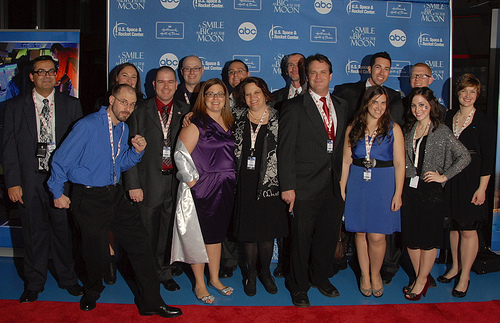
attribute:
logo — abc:
[235, 21, 259, 45]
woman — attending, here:
[338, 86, 404, 297]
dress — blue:
[345, 120, 404, 236]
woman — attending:
[176, 77, 235, 304]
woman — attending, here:
[444, 73, 493, 303]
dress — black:
[445, 106, 494, 232]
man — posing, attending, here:
[44, 84, 186, 318]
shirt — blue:
[44, 106, 150, 198]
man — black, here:
[2, 54, 89, 304]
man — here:
[277, 53, 348, 307]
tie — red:
[319, 97, 332, 122]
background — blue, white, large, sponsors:
[104, 0, 456, 111]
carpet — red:
[2, 299, 500, 323]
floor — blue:
[2, 255, 500, 303]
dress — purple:
[187, 112, 240, 246]